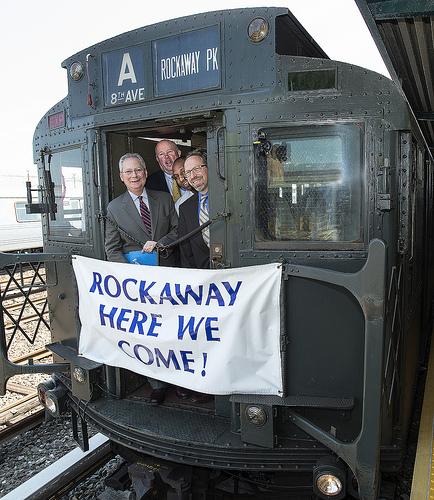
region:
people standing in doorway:
[94, 114, 222, 266]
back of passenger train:
[34, 8, 398, 489]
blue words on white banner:
[72, 262, 284, 396]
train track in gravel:
[4, 422, 107, 498]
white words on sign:
[100, 21, 224, 110]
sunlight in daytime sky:
[0, 1, 388, 98]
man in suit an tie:
[106, 153, 176, 262]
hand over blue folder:
[122, 238, 162, 262]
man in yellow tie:
[151, 139, 185, 202]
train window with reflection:
[256, 120, 368, 247]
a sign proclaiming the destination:
[71, 254, 285, 395]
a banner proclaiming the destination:
[66, 251, 280, 392]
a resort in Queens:
[89, 270, 245, 309]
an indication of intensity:
[200, 349, 209, 381]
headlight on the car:
[43, 391, 59, 416]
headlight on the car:
[316, 465, 344, 496]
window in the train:
[43, 145, 85, 241]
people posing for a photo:
[105, 139, 209, 266]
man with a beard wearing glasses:
[174, 152, 212, 269]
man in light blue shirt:
[171, 157, 193, 215]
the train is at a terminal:
[24, 4, 425, 497]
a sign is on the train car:
[68, 250, 288, 401]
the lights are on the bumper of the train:
[33, 390, 364, 499]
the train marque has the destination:
[95, 21, 234, 103]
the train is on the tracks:
[3, 415, 368, 498]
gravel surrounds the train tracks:
[7, 400, 134, 495]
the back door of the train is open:
[105, 114, 225, 428]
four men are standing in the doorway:
[107, 130, 216, 271]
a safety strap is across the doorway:
[95, 211, 232, 254]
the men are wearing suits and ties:
[103, 137, 217, 267]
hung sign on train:
[68, 247, 291, 403]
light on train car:
[311, 466, 352, 498]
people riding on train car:
[101, 130, 213, 263]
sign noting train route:
[92, 29, 224, 111]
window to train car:
[249, 122, 371, 252]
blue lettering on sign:
[89, 267, 105, 297]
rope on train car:
[173, 221, 211, 242]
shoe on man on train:
[149, 386, 168, 410]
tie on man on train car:
[132, 192, 153, 234]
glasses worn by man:
[181, 164, 207, 176]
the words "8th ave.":
[104, 84, 150, 110]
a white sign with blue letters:
[66, 250, 285, 403]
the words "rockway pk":
[155, 41, 223, 82]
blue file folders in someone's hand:
[114, 241, 162, 272]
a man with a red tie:
[99, 144, 177, 267]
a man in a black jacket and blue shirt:
[178, 148, 216, 269]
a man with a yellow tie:
[143, 135, 186, 207]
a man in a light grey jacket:
[170, 153, 198, 217]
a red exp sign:
[43, 109, 70, 134]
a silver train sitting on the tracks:
[5, 163, 92, 259]